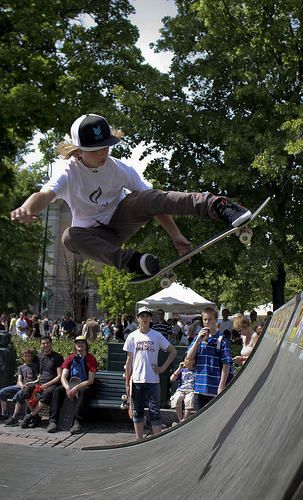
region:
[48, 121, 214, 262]
boy wearing white shirt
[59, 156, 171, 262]
boy wearing brown pants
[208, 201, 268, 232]
black and white skate shoes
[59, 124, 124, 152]
black and white hat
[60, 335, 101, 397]
boy wearing red shirt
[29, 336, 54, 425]
man sitting on park bench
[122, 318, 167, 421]
boy holding a skateboard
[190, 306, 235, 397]
boy drinking a soda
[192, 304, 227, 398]
boy wearing blue shirt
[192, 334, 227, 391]
blue shirt with red and white stripes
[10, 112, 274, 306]
Boy is wearing cap.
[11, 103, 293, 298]
Cap is black and white.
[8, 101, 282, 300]
Boy is on skateboard.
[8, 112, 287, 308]
Boy is wearing pants.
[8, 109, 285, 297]
The pants are brown.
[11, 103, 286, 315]
Boy is wearing shirt.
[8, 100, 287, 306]
The shirt is white.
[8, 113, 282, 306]
The skateboard has wheels.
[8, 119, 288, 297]
Skateboard wheels are white.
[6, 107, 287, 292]
Skateboard wheels are round.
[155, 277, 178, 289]
wheel on the skateboard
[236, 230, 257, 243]
another wheel on skateboard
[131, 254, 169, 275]
foot on the skateboard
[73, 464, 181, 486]
part of the skateboard ramp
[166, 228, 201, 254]
boy's hand touching skateboard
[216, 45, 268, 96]
leaves on the tree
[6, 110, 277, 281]
young man on skateboard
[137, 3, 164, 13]
part of the sky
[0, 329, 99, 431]
spectators on the bench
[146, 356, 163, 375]
boy's hand on shirt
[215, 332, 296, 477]
the shadow is on the ramp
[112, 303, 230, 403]
the boys are watching the skater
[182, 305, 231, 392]
the boy is drinking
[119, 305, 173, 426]
the boy is holding a skateboard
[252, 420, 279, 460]
the ramp is gray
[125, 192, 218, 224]
the pants are brown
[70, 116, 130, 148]
the cap is black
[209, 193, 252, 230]
the shoes are black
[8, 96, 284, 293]
the boy is skateboarding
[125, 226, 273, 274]
the skateboard is black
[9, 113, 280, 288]
Young boy doing tricks on skateboard.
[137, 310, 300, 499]
Gray colored skateboard ramp.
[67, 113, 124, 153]
Young boy wearing white and navy blue cap.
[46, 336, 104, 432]
Man in red shirt sitting on bench holding skateboard.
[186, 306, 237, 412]
Boy in striped shirt sipping drink.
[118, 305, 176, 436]
Young man dressed in white t-shirt standing with hand on hip holding skateboard.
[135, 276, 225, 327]
Whie tent set up in background.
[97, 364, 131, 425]
Green bench set up next to skateboard ramp.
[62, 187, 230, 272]
Young boy dressed in brown pants.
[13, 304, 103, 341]
People standing in background beyond skateboard ramp.